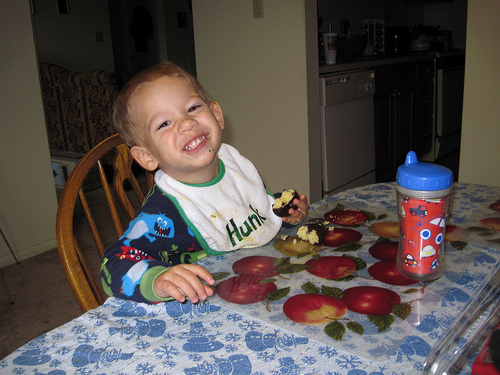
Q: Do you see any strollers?
A: No, there are no strollers.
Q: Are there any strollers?
A: No, there are no strollers.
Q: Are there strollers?
A: No, there are no strollers.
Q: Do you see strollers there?
A: No, there are no strollers.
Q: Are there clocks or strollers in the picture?
A: No, there are no strollers or clocks.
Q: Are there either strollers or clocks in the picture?
A: No, there are no strollers or clocks.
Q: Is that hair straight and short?
A: No, the hair is short but curly.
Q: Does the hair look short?
A: Yes, the hair is short.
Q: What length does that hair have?
A: The hair has short length.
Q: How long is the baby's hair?
A: The hair is short.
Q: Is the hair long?
A: No, the hair is short.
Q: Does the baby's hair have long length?
A: No, the hair is short.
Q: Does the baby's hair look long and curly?
A: No, the hair is curly but short.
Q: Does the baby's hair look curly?
A: Yes, the hair is curly.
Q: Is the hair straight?
A: No, the hair is curly.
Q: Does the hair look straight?
A: No, the hair is curly.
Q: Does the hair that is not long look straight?
A: No, the hair is curly.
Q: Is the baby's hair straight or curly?
A: The hair is curly.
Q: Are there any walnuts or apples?
A: Yes, there is an apple.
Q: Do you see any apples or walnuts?
A: Yes, there is an apple.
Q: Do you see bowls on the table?
A: No, there is an apple on the table.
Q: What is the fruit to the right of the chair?
A: The fruit is an apple.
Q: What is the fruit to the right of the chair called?
A: The fruit is an apple.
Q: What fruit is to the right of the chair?
A: The fruit is an apple.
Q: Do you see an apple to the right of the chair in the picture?
A: Yes, there is an apple to the right of the chair.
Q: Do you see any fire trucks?
A: No, there are no fire trucks.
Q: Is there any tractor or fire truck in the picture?
A: No, there are no fire trucks or tractors.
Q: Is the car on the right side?
A: Yes, the car is on the right of the image.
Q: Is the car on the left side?
A: No, the car is on the right of the image.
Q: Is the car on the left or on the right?
A: The car is on the right of the image.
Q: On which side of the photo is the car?
A: The car is on the right of the image.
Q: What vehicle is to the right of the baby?
A: The vehicle is a car.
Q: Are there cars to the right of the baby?
A: Yes, there is a car to the right of the baby.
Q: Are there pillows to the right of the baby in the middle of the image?
A: No, there is a car to the right of the baby.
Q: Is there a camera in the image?
A: Yes, there is a camera.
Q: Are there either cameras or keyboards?
A: Yes, there is a camera.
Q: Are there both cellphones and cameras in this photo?
A: No, there is a camera but no cell phones.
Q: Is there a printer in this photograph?
A: No, there are no printers.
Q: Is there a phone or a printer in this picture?
A: No, there are no printers or phones.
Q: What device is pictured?
A: The device is a camera.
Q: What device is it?
A: The device is a camera.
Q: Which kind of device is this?
A: This is a camera.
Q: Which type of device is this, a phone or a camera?
A: This is a camera.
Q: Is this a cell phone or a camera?
A: This is a camera.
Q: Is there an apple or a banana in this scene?
A: Yes, there is an apple.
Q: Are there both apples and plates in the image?
A: No, there is an apple but no plates.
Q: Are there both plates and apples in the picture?
A: No, there is an apple but no plates.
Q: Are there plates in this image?
A: No, there are no plates.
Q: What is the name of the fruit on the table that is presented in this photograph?
A: The fruit is an apple.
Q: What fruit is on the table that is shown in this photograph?
A: The fruit is an apple.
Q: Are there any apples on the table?
A: Yes, there is an apple on the table.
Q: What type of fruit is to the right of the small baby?
A: The fruit is an apple.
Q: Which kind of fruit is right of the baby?
A: The fruit is an apple.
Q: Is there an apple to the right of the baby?
A: Yes, there is an apple to the right of the baby.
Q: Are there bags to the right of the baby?
A: No, there is an apple to the right of the baby.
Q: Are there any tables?
A: Yes, there is a table.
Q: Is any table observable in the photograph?
A: Yes, there is a table.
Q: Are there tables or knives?
A: Yes, there is a table.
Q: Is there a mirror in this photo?
A: No, there are no mirrors.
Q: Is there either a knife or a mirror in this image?
A: No, there are no mirrors or knives.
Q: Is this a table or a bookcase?
A: This is a table.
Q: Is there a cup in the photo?
A: Yes, there is a cup.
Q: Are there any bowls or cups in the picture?
A: Yes, there is a cup.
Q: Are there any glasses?
A: No, there are no glasses.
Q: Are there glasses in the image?
A: No, there are no glasses.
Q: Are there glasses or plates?
A: No, there are no glasses or plates.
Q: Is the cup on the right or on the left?
A: The cup is on the right of the image.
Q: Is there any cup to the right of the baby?
A: Yes, there is a cup to the right of the baby.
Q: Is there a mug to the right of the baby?
A: No, there is a cup to the right of the baby.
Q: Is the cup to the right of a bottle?
A: No, the cup is to the right of the baby.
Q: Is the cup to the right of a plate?
A: No, the cup is to the right of an apple.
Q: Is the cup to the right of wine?
A: No, the cup is to the right of the food.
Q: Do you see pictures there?
A: No, there are no pictures.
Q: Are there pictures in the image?
A: No, there are no pictures.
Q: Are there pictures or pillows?
A: No, there are no pictures or pillows.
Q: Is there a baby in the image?
A: Yes, there is a baby.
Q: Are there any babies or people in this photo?
A: Yes, there is a baby.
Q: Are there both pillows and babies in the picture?
A: No, there is a baby but no pillows.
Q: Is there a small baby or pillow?
A: Yes, there is a small baby.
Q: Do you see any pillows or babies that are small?
A: Yes, the baby is small.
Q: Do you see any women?
A: No, there are no women.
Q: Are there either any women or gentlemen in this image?
A: No, there are no women or gentlemen.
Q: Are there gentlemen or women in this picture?
A: No, there are no women or gentlemen.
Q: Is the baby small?
A: Yes, the baby is small.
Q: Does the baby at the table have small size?
A: Yes, the baby is small.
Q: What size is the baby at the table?
A: The baby is small.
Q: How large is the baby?
A: The baby is small.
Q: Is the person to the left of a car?
A: Yes, the baby is to the left of a car.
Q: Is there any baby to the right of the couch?
A: Yes, there is a baby to the right of the couch.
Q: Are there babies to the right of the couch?
A: Yes, there is a baby to the right of the couch.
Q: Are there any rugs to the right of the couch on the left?
A: No, there is a baby to the right of the couch.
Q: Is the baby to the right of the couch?
A: Yes, the baby is to the right of the couch.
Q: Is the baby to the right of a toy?
A: No, the baby is to the right of the couch.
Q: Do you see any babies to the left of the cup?
A: Yes, there is a baby to the left of the cup.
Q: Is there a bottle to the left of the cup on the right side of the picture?
A: No, there is a baby to the left of the cup.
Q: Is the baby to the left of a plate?
A: No, the baby is to the left of the cup.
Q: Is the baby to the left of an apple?
A: Yes, the baby is to the left of an apple.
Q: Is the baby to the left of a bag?
A: No, the baby is to the left of an apple.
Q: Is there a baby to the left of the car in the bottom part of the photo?
A: Yes, there is a baby to the left of the car.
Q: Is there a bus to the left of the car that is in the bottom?
A: No, there is a baby to the left of the car.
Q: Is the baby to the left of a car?
A: Yes, the baby is to the left of a car.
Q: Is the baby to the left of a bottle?
A: No, the baby is to the left of a car.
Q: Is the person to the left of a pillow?
A: No, the baby is to the left of a car.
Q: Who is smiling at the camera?
A: The baby is smiling at the camera.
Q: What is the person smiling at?
A: The baby is smiling at the camera.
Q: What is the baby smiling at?
A: The baby is smiling at the camera.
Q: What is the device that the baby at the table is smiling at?
A: The device is a camera.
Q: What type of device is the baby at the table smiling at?
A: The baby is smiling at the camera.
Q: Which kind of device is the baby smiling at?
A: The baby is smiling at the camera.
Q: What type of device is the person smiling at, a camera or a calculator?
A: The baby is smiling at a camera.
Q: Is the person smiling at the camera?
A: Yes, the baby is smiling at the camera.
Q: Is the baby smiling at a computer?
A: No, the baby is smiling at the camera.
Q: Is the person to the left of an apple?
A: Yes, the baby is to the left of an apple.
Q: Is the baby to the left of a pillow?
A: No, the baby is to the left of an apple.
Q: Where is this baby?
A: The baby is at the table.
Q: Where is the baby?
A: The baby is at the table.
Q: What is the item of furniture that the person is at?
A: The piece of furniture is a table.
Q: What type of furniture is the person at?
A: The baby is at the table.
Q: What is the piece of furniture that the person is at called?
A: The piece of furniture is a table.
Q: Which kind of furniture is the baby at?
A: The baby is at the table.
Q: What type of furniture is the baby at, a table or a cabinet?
A: The baby is at a table.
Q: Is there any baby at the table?
A: Yes, there is a baby at the table.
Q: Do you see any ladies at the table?
A: No, there is a baby at the table.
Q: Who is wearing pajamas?
A: The baby is wearing pajamas.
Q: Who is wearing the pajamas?
A: The baby is wearing pajamas.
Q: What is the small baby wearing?
A: The baby is wearing pajamas.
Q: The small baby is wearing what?
A: The baby is wearing pajamas.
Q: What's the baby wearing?
A: The baby is wearing pajamas.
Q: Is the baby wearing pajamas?
A: Yes, the baby is wearing pajamas.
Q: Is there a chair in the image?
A: Yes, there is a chair.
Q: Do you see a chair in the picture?
A: Yes, there is a chair.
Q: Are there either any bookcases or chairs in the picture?
A: Yes, there is a chair.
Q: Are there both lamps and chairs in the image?
A: No, there is a chair but no lamps.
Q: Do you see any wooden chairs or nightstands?
A: Yes, there is a wood chair.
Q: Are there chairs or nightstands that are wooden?
A: Yes, the chair is wooden.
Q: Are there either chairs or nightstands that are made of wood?
A: Yes, the chair is made of wood.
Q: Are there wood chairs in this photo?
A: Yes, there is a wood chair.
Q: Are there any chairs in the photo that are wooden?
A: Yes, there is a chair that is wooden.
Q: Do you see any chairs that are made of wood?
A: Yes, there is a chair that is made of wood.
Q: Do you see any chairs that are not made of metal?
A: Yes, there is a chair that is made of wood.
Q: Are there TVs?
A: No, there are no tvs.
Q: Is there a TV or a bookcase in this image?
A: No, there are no televisions or bookcases.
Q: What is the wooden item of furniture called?
A: The piece of furniture is a chair.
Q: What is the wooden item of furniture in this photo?
A: The piece of furniture is a chair.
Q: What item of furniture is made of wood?
A: The piece of furniture is a chair.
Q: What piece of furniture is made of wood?
A: The piece of furniture is a chair.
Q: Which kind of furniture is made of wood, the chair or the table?
A: The chair is made of wood.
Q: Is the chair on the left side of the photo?
A: Yes, the chair is on the left of the image.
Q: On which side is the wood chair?
A: The chair is on the left of the image.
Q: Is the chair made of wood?
A: Yes, the chair is made of wood.